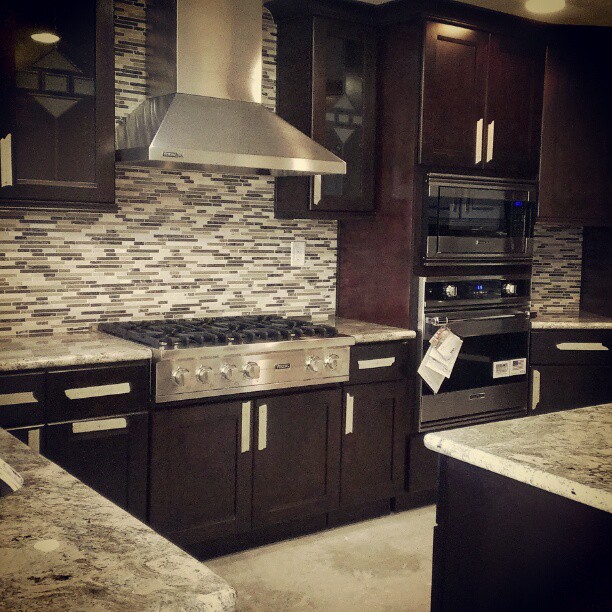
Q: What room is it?
A: It is a kitchen.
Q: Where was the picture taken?
A: It was taken at the kitchen.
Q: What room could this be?
A: It is a kitchen.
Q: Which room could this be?
A: It is a kitchen.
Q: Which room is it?
A: It is a kitchen.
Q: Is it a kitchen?
A: Yes, it is a kitchen.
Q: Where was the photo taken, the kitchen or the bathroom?
A: It was taken at the kitchen.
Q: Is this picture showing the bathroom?
A: No, the picture is showing the kitchen.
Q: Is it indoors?
A: Yes, it is indoors.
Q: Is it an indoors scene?
A: Yes, it is indoors.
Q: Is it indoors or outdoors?
A: It is indoors.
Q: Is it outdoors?
A: No, it is indoors.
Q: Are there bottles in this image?
A: No, there are no bottles.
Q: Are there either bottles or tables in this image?
A: No, there are no bottles or tables.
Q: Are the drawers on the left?
A: Yes, the drawers are on the left of the image.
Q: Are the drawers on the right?
A: No, the drawers are on the left of the image.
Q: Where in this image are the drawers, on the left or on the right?
A: The drawers are on the left of the image.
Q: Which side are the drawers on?
A: The drawers are on the left of the image.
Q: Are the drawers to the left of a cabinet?
A: Yes, the drawers are to the left of a cabinet.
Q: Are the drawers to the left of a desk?
A: No, the drawers are to the left of a cabinet.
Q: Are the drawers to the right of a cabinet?
A: No, the drawers are to the left of a cabinet.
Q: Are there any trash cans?
A: No, there are no trash cans.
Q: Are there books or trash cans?
A: No, there are no trash cans or books.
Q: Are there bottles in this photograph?
A: No, there are no bottles.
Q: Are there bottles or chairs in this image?
A: No, there are no bottles or chairs.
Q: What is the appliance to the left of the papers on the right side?
A: The appliance is a stove.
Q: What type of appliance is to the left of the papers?
A: The appliance is a stove.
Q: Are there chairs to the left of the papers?
A: No, there is a stove to the left of the papers.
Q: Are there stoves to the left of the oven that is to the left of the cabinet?
A: Yes, there is a stove to the left of the oven.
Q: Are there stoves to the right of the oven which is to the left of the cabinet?
A: No, the stove is to the left of the oven.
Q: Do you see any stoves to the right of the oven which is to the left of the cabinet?
A: No, the stove is to the left of the oven.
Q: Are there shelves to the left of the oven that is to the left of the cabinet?
A: No, there is a stove to the left of the oven.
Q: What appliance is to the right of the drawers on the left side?
A: The appliance is a stove.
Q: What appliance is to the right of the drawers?
A: The appliance is a stove.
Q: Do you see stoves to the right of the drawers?
A: Yes, there is a stove to the right of the drawers.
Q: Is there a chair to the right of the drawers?
A: No, there is a stove to the right of the drawers.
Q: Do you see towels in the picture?
A: No, there are no towels.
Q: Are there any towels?
A: No, there are no towels.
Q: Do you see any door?
A: Yes, there is a door.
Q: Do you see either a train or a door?
A: Yes, there is a door.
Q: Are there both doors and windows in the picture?
A: No, there is a door but no windows.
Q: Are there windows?
A: No, there are no windows.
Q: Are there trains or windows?
A: No, there are no windows or trains.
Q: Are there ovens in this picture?
A: Yes, there is an oven.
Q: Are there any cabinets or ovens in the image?
A: Yes, there is an oven.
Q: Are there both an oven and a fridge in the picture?
A: No, there is an oven but no refrigerators.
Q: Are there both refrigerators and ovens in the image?
A: No, there is an oven but no refrigerators.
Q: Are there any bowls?
A: No, there are no bowls.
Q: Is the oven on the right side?
A: Yes, the oven is on the right of the image.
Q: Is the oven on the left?
A: No, the oven is on the right of the image.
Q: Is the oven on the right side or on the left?
A: The oven is on the right of the image.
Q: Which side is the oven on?
A: The oven is on the right of the image.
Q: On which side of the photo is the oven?
A: The oven is on the right of the image.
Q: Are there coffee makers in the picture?
A: No, there are no coffee makers.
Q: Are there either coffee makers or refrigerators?
A: No, there are no coffee makers or refrigerators.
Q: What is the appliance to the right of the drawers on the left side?
A: The appliance is a stove.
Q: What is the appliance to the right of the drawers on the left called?
A: The appliance is a stove.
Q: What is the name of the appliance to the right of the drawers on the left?
A: The appliance is a stove.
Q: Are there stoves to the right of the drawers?
A: Yes, there is a stove to the right of the drawers.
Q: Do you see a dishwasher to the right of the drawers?
A: No, there is a stove to the right of the drawers.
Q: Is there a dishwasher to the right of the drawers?
A: No, there is a stove to the right of the drawers.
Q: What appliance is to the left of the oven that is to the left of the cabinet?
A: The appliance is a stove.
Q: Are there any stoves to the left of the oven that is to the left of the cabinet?
A: Yes, there is a stove to the left of the oven.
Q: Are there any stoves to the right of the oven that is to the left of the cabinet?
A: No, the stove is to the left of the oven.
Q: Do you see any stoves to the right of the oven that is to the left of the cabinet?
A: No, the stove is to the left of the oven.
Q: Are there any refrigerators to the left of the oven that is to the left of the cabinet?
A: No, there is a stove to the left of the oven.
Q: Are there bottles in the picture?
A: No, there are no bottles.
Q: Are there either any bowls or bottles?
A: No, there are no bottles or bowls.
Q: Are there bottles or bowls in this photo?
A: No, there are no bottles or bowls.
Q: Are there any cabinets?
A: Yes, there is a cabinet.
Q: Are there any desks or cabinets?
A: Yes, there is a cabinet.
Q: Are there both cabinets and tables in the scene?
A: No, there is a cabinet but no tables.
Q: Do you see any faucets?
A: No, there are no faucets.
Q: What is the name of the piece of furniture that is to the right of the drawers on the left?
A: The piece of furniture is a cabinet.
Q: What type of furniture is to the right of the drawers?
A: The piece of furniture is a cabinet.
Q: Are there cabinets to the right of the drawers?
A: Yes, there is a cabinet to the right of the drawers.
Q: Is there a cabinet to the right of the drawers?
A: Yes, there is a cabinet to the right of the drawers.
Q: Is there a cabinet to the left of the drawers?
A: No, the cabinet is to the right of the drawers.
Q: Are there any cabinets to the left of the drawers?
A: No, the cabinet is to the right of the drawers.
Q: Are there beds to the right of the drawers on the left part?
A: No, there is a cabinet to the right of the drawers.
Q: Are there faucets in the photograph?
A: No, there are no faucets.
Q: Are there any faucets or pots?
A: No, there are no faucets or pots.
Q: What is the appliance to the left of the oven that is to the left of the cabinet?
A: The appliance is a stove.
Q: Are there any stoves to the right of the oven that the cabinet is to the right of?
A: No, the stove is to the left of the oven.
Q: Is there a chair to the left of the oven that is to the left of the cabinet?
A: No, there is a stove to the left of the oven.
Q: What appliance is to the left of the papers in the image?
A: The appliance is a stove.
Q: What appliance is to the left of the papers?
A: The appliance is a stove.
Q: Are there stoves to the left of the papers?
A: Yes, there is a stove to the left of the papers.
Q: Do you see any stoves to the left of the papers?
A: Yes, there is a stove to the left of the papers.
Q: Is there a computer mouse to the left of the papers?
A: No, there is a stove to the left of the papers.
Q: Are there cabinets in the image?
A: Yes, there is a cabinet.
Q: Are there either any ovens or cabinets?
A: Yes, there is a cabinet.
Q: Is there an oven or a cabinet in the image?
A: Yes, there is a cabinet.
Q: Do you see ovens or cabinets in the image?
A: Yes, there is a cabinet.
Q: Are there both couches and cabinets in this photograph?
A: No, there is a cabinet but no couches.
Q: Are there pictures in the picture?
A: No, there are no pictures.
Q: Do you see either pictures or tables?
A: No, there are no pictures or tables.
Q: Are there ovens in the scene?
A: Yes, there is an oven.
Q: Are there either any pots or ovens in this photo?
A: Yes, there is an oven.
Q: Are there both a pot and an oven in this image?
A: No, there is an oven but no pots.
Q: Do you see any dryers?
A: No, there are no dryers.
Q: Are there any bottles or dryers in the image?
A: No, there are no dryers or bottles.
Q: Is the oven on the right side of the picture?
A: Yes, the oven is on the right of the image.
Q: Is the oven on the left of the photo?
A: No, the oven is on the right of the image.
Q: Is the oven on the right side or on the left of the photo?
A: The oven is on the right of the image.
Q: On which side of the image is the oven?
A: The oven is on the right of the image.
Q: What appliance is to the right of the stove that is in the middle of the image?
A: The appliance is an oven.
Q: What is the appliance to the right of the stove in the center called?
A: The appliance is an oven.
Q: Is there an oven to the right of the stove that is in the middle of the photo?
A: Yes, there is an oven to the right of the stove.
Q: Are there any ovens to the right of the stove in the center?
A: Yes, there is an oven to the right of the stove.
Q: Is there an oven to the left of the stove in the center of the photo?
A: No, the oven is to the right of the stove.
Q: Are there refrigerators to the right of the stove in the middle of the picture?
A: No, there is an oven to the right of the stove.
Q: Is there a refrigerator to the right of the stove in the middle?
A: No, there is an oven to the right of the stove.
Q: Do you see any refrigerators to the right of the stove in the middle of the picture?
A: No, there is an oven to the right of the stove.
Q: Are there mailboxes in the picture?
A: No, there are no mailboxes.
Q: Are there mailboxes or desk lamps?
A: No, there are no mailboxes or desk lamps.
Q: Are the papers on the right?
A: Yes, the papers are on the right of the image.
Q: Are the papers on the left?
A: No, the papers are on the right of the image.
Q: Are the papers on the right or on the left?
A: The papers are on the right of the image.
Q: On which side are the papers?
A: The papers are on the right of the image.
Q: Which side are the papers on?
A: The papers are on the right of the image.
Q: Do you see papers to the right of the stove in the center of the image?
A: Yes, there are papers to the right of the stove.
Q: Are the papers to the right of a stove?
A: Yes, the papers are to the right of a stove.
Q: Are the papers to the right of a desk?
A: No, the papers are to the right of a stove.